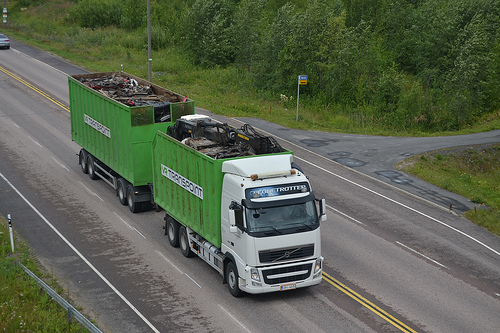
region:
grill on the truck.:
[268, 250, 304, 260]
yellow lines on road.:
[374, 305, 396, 322]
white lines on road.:
[398, 237, 438, 271]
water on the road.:
[117, 259, 148, 286]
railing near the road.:
[72, 306, 94, 326]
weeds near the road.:
[20, 297, 53, 329]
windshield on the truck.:
[256, 208, 306, 220]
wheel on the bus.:
[223, 265, 234, 295]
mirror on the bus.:
[225, 208, 237, 235]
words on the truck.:
[250, 183, 305, 196]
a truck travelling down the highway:
[53, 45, 340, 317]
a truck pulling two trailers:
[59, 58, 329, 304]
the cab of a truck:
[222, 178, 327, 298]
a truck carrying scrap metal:
[47, 55, 363, 306]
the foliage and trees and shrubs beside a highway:
[211, 0, 490, 106]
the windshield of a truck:
[245, 208, 323, 235]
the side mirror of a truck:
[223, 203, 238, 236]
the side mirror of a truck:
[316, 196, 335, 221]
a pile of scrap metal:
[173, 111, 278, 157]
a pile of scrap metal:
[77, 67, 176, 107]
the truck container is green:
[57, 74, 228, 246]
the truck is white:
[220, 155, 339, 317]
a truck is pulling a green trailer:
[61, 60, 328, 304]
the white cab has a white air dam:
[218, 156, 328, 296]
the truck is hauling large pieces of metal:
[151, 110, 320, 234]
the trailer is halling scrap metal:
[66, 63, 192, 198]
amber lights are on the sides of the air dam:
[243, 165, 298, 181]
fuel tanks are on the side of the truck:
[191, 235, 225, 272]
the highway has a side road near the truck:
[43, 73, 499, 285]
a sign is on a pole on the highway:
[290, 70, 311, 127]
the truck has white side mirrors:
[222, 197, 329, 241]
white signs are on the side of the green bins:
[72, 110, 267, 204]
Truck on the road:
[58, 42, 350, 319]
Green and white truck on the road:
[63, 43, 340, 306]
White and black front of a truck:
[230, 164, 338, 306]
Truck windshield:
[236, 198, 325, 238]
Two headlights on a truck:
[242, 258, 331, 300]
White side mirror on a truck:
[222, 198, 247, 238]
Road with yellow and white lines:
[345, 162, 446, 331]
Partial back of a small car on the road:
[0, 30, 30, 87]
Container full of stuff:
[65, 65, 196, 111]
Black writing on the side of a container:
[154, 156, 206, 204]